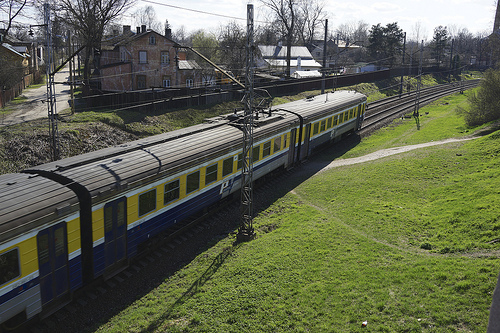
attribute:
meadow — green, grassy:
[39, 76, 498, 332]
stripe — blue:
[2, 101, 357, 306]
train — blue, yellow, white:
[12, 73, 427, 303]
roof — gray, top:
[113, 132, 193, 174]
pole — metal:
[321, 18, 329, 97]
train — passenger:
[1, 82, 355, 331]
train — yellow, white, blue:
[2, 66, 397, 273]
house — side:
[97, 25, 203, 92]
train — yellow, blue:
[23, 86, 371, 244]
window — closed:
[136, 187, 158, 218]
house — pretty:
[93, 24, 200, 101]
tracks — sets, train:
[356, 78, 454, 131]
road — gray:
[3, 50, 77, 125]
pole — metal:
[238, 4, 251, 240]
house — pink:
[54, 8, 277, 126]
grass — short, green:
[284, 217, 480, 317]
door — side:
[101, 195, 131, 280]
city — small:
[5, 6, 395, 117]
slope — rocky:
[14, 98, 112, 148]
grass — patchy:
[65, 109, 99, 122]